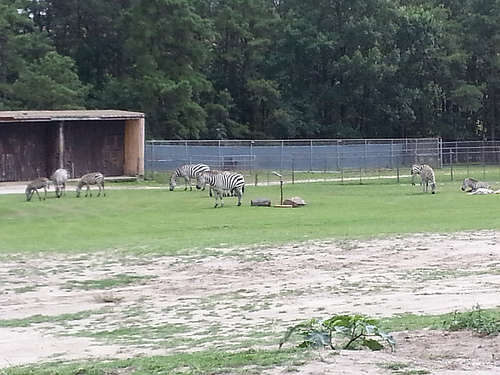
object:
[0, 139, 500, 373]
exhibit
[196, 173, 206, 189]
head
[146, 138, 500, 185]
fence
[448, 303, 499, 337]
leaves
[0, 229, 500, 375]
dirt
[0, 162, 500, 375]
grass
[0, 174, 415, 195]
dirt path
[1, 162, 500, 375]
pasture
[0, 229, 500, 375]
patches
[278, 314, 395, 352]
plant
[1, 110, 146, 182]
wooden shed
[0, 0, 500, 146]
green trees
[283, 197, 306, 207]
rocks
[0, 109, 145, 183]
structure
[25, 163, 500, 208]
zebra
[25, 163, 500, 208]
group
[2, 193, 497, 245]
field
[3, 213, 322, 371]
ground